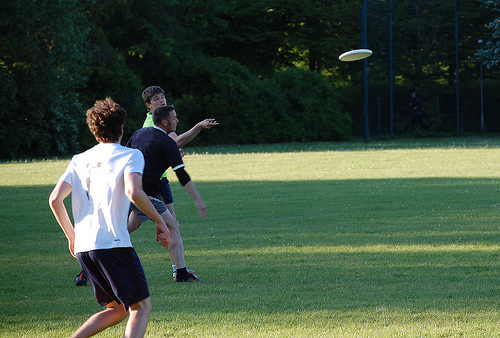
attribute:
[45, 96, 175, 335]
man — playing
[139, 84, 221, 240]
person — lookig up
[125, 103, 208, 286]
guy — black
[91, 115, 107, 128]
hair — curly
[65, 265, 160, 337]
legs — white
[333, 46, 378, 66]
frisbee — flying, white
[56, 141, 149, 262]
shirt — white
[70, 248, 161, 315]
shorts — dark, blue nylon, black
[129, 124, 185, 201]
shirt — black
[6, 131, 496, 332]
field — green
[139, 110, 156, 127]
shirt — green